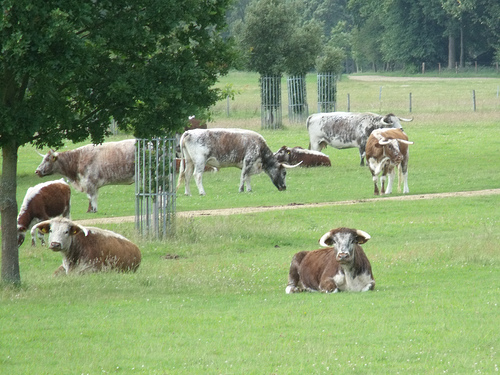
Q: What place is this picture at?
A: It is at the field.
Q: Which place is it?
A: It is a field.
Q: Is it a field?
A: Yes, it is a field.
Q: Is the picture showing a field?
A: Yes, it is showing a field.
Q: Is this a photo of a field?
A: Yes, it is showing a field.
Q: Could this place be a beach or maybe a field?
A: It is a field.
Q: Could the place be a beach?
A: No, it is a field.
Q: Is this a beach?
A: No, it is a field.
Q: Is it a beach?
A: No, it is a field.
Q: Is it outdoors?
A: Yes, it is outdoors.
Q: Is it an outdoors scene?
A: Yes, it is outdoors.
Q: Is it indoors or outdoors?
A: It is outdoors.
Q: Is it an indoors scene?
A: No, it is outdoors.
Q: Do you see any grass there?
A: Yes, there is grass.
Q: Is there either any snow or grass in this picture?
A: Yes, there is grass.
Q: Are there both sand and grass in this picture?
A: No, there is grass but no sand.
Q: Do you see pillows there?
A: No, there are no pillows.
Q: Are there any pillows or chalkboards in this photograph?
A: No, there are no pillows or chalkboards.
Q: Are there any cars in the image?
A: No, there are no cars.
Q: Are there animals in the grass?
A: Yes, there is an animal in the grass.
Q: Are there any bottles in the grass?
A: No, there is an animal in the grass.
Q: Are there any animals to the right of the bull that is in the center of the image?
A: Yes, there is an animal to the right of the bull.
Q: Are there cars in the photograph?
A: No, there are no cars.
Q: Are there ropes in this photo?
A: No, there are no ropes.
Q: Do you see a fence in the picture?
A: Yes, there is a fence.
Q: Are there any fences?
A: Yes, there is a fence.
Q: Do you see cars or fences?
A: Yes, there is a fence.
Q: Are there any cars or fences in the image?
A: Yes, there is a fence.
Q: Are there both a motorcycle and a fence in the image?
A: No, there is a fence but no motorcycles.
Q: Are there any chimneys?
A: No, there are no chimneys.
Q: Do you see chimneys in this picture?
A: No, there are no chimneys.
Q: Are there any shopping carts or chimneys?
A: No, there are no chimneys or shopping carts.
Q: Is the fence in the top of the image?
A: Yes, the fence is in the top of the image.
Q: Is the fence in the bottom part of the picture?
A: No, the fence is in the top of the image.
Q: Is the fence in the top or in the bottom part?
A: The fence is in the top of the image.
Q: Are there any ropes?
A: No, there are no ropes.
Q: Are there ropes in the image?
A: No, there are no ropes.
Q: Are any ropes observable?
A: No, there are no ropes.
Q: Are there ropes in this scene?
A: No, there are no ropes.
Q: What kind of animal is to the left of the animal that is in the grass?
A: The animal is a bull.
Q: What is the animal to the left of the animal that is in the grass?
A: The animal is a bull.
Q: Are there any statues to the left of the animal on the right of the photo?
A: No, there is a bull to the left of the animal.